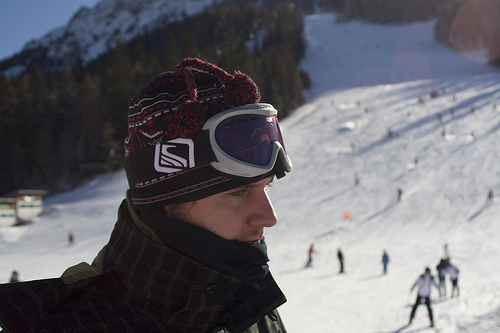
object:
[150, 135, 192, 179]
logo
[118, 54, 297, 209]
hat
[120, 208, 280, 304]
scarf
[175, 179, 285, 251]
man's face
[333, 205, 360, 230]
orange object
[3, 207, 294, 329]
jacket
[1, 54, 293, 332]
man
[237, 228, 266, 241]
beard